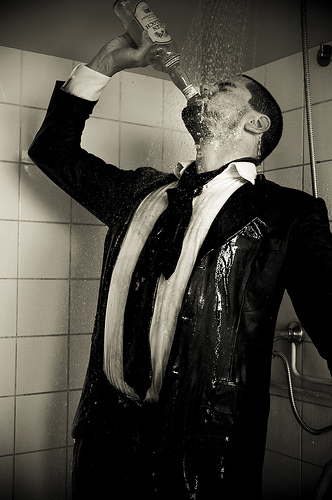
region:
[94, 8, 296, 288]
man standing in shower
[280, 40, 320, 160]
hose hanging from shower head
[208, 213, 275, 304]
reflection on wet jacket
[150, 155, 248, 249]
tie around man's neck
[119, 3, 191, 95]
bottle in man's hand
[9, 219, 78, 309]
square tiles on wall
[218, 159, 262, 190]
open collar on dress shirt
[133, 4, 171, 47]
label on glass bottle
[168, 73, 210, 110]
bottle in man's mouth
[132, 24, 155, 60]
thumb on side of bottle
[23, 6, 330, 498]
Man takes a shower with cloths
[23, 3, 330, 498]
Man drinks from a bottle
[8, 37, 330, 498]
Man wears black suit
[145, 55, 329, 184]
Hair of man is short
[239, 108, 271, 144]
Left ear of man can be seen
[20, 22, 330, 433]
Man wears long sleeve shirt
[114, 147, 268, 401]
Tie is around neck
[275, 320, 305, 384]
Handle of shower is silver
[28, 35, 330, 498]
Man is wet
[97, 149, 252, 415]
Tie is messy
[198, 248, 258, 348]
reflection on wet jacket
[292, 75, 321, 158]
hose hanging from shower head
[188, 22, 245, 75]
water dropping from shower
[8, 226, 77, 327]
tile on shower wall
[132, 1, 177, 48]
label on alcohol bottle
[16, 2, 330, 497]
Man drinking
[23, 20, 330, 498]
Man is under a shower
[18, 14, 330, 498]
Man with tie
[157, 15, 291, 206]
Water falls on face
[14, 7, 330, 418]
Man wears long white shirt sleeve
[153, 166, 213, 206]
Knot of tie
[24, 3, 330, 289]
Man holds a bottle in right arm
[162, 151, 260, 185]
Collar of shirt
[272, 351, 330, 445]
Tube behind man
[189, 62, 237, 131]
water on man's face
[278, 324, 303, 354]
bathroom hardware on wall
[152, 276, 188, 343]
wet white shirt on man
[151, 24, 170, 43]
picture on bottle label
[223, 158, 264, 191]
open collar of dress shirt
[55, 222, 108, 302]
man's shadow on wall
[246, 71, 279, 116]
short dark hair on head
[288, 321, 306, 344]
reflection on metal fixture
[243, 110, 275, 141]
ear on man's head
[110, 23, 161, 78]
hand holding glass bottle